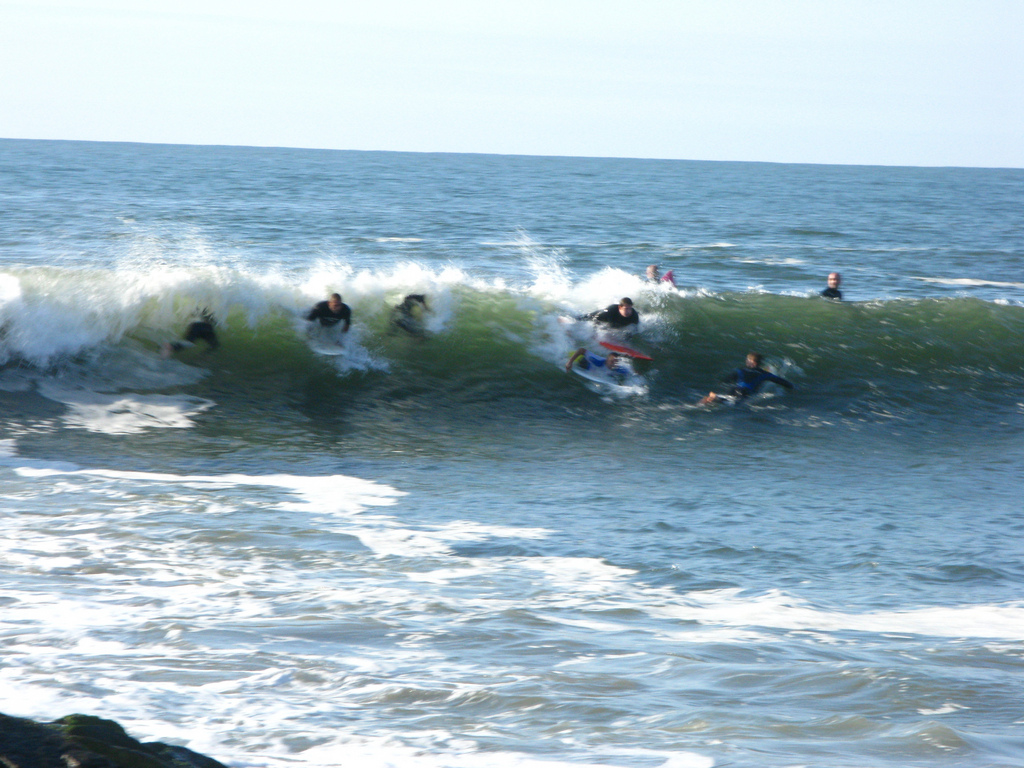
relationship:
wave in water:
[0, 232, 1023, 398] [4, 130, 992, 731]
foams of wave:
[309, 199, 552, 325] [15, 163, 953, 499]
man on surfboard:
[233, 245, 445, 384] [306, 340, 404, 393]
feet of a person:
[692, 383, 740, 409] [556, 271, 682, 380]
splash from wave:
[133, 234, 477, 312] [6, 243, 990, 438]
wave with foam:
[8, 232, 991, 507] [36, 346, 225, 459]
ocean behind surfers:
[4, 134, 985, 307] [159, 260, 872, 418]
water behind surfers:
[6, 139, 992, 328] [178, 256, 861, 431]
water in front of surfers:
[3, 376, 991, 765] [176, 255, 861, 405]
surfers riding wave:
[158, 294, 233, 368] [11, 258, 815, 414]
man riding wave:
[302, 290, 355, 346] [11, 258, 815, 414]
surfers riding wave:
[546, 335, 661, 422] [11, 258, 815, 414]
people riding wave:
[576, 295, 645, 334] [11, 258, 815, 414]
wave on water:
[0, 232, 1023, 398] [4, 130, 992, 731]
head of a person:
[607, 288, 638, 321] [589, 294, 657, 385]